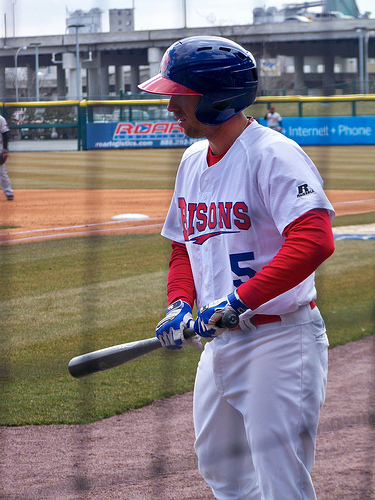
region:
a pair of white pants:
[192, 326, 322, 499]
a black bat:
[69, 316, 239, 379]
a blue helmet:
[134, 27, 258, 130]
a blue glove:
[188, 288, 246, 337]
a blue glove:
[146, 295, 197, 358]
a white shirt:
[159, 118, 345, 332]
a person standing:
[0, 114, 15, 206]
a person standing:
[135, 33, 339, 498]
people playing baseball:
[0, 0, 367, 498]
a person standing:
[262, 104, 284, 131]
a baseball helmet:
[152, 45, 276, 161]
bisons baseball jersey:
[172, 160, 275, 295]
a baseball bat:
[64, 320, 163, 390]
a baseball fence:
[54, 107, 146, 138]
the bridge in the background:
[59, 44, 124, 102]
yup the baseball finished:
[106, 186, 365, 255]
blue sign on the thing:
[79, 89, 141, 132]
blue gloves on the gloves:
[138, 304, 236, 352]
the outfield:
[96, 150, 147, 175]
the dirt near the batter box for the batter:
[106, 432, 229, 471]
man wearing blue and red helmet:
[129, 30, 271, 109]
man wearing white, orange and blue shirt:
[140, 137, 345, 303]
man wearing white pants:
[185, 340, 345, 493]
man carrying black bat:
[58, 329, 160, 378]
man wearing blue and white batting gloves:
[148, 291, 248, 349]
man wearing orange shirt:
[246, 226, 347, 315]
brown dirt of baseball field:
[17, 424, 186, 489]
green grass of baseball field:
[10, 246, 151, 331]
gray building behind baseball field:
[13, 21, 136, 137]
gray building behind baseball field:
[267, 11, 366, 93]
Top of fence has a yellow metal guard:
[8, 95, 146, 108]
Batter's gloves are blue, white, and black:
[158, 298, 244, 348]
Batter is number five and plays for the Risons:
[172, 195, 268, 288]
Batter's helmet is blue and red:
[137, 35, 259, 125]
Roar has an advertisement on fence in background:
[89, 123, 185, 147]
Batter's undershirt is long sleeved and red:
[164, 139, 335, 307]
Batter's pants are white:
[194, 337, 327, 496]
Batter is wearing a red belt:
[228, 305, 328, 333]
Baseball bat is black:
[64, 335, 160, 377]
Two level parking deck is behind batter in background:
[243, 0, 371, 22]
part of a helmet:
[204, 63, 238, 98]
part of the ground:
[141, 458, 178, 494]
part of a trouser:
[193, 390, 233, 421]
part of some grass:
[75, 388, 100, 418]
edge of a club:
[47, 325, 110, 378]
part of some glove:
[201, 316, 219, 342]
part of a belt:
[254, 303, 271, 332]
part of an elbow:
[314, 235, 335, 269]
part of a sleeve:
[276, 251, 302, 272]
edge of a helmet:
[182, 110, 232, 137]